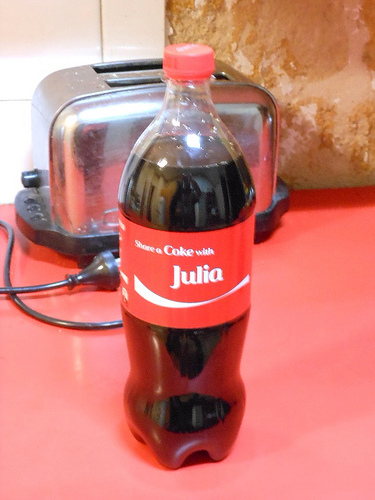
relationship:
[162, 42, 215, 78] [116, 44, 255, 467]
bottle cap on bottle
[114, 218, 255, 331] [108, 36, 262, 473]
label on bottle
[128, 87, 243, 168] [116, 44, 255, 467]
drops inside bottle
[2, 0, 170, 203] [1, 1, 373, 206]
tiles on wall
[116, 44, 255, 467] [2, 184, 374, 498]
bottle sitting on counter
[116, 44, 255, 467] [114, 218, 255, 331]
bottle with label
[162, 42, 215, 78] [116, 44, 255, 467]
bottle cap of bottle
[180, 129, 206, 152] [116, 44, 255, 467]
light reflected in bottle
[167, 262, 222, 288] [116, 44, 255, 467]
name on bottle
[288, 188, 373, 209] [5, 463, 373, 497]
shadow on counter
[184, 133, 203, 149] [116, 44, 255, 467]
glare on bottle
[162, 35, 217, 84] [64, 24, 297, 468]
top on bottle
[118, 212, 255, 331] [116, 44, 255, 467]
label on bottle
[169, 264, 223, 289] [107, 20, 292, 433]
name on coke bottle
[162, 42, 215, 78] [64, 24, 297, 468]
bottle cap of bottle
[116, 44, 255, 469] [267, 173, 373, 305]
bottle on table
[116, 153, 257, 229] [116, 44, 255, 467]
dark liquid in a bottle